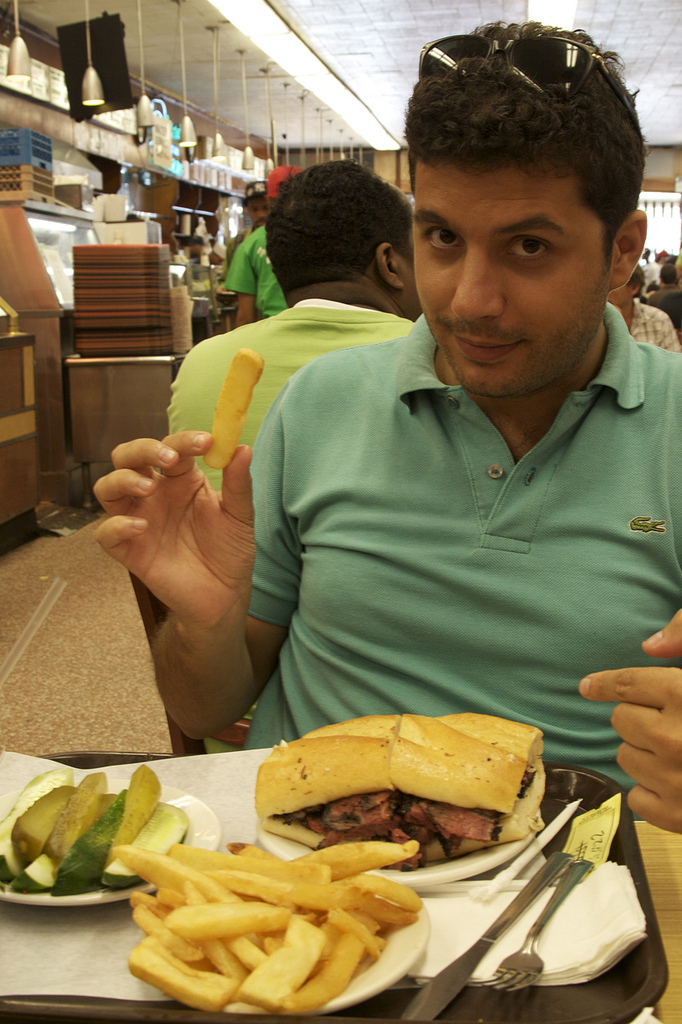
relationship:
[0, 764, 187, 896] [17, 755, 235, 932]
pickles sit on plate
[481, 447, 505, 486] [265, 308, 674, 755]
button on shirt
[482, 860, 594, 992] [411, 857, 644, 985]
fork on napkin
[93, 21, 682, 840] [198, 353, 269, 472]
man holding french fry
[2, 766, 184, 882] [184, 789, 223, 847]
pickles on top of a plate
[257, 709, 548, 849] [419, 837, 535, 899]
sandwich on top of a plate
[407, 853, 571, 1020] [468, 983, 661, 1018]
knife on top of a tray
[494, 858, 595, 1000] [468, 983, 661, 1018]
fork on top of a tray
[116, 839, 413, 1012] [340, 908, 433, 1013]
french fry's on top of a plate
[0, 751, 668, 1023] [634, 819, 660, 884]
tray on top of a table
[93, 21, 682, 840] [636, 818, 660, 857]
man next to a table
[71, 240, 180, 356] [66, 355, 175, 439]
trays on top of a cart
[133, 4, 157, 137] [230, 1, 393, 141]
hanging lights mounted to ceiling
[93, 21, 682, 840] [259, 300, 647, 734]
man wearing a shirt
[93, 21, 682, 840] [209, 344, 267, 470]
man holding french fry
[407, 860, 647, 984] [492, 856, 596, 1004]
napkin underneath utensil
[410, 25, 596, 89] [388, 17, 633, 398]
glasses on h head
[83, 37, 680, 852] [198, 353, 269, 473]
man with a french fry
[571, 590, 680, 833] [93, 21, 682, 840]
fingers of man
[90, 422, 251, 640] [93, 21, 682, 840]
hand of man